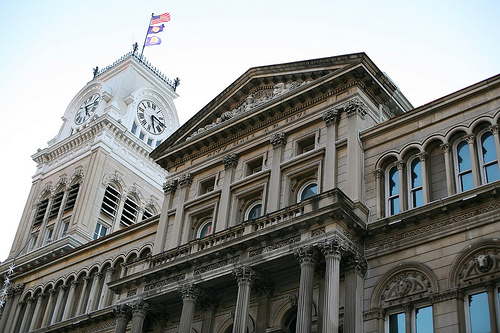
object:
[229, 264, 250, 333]
pillar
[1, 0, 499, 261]
sky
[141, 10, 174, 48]
flag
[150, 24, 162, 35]
circle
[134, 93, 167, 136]
clock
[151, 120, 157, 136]
hand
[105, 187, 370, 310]
balcony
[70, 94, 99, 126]
clock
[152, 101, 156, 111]
numeral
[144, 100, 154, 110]
numeral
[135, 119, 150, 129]
numeral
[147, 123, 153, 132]
numeral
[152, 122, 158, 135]
numeral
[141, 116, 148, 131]
numeral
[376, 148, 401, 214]
window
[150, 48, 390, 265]
facade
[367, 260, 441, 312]
decorative pattern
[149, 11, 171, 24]
american flag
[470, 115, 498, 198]
window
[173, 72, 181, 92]
iron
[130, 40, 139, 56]
iron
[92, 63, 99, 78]
iron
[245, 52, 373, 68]
roof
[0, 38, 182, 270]
building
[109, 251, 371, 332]
column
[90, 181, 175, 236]
window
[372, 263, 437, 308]
gargoyles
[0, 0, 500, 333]
tower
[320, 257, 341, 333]
pillar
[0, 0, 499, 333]
building